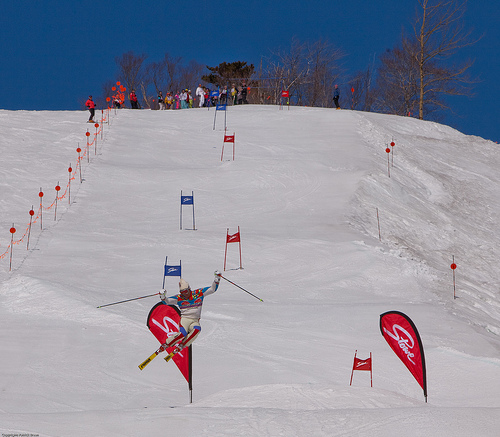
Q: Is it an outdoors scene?
A: Yes, it is outdoors.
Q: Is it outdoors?
A: Yes, it is outdoors.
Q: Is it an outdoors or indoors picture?
A: It is outdoors.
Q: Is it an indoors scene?
A: No, it is outdoors.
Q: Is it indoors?
A: No, it is outdoors.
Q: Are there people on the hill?
A: Yes, there is a person on the hill.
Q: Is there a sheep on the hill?
A: No, there is a person on the hill.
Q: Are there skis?
A: Yes, there are skis.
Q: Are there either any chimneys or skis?
A: Yes, there are skis.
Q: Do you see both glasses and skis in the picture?
A: No, there are skis but no glasses.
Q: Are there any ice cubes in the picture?
A: No, there are no ice cubes.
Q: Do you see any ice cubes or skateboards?
A: No, there are no ice cubes or skateboards.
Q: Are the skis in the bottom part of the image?
A: Yes, the skis are in the bottom of the image.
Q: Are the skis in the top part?
A: No, the skis are in the bottom of the image.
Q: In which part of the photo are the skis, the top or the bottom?
A: The skis are in the bottom of the image.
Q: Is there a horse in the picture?
A: No, there are no horses.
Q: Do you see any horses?
A: No, there are no horses.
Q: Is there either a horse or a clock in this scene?
A: No, there are no horses or clocks.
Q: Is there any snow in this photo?
A: Yes, there is snow.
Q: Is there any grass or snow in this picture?
A: Yes, there is snow.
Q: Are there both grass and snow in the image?
A: No, there is snow but no grass.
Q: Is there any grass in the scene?
A: No, there is no grass.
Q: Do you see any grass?
A: No, there is no grass.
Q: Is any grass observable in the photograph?
A: No, there is no grass.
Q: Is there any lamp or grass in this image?
A: No, there are no grass or lamps.